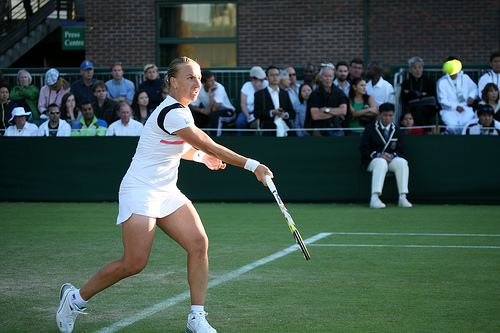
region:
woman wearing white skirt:
[132, 196, 152, 209]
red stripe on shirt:
[156, 138, 181, 144]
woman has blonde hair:
[176, 61, 181, 68]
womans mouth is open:
[191, 87, 202, 97]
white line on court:
[309, 225, 329, 241]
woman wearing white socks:
[68, 288, 81, 303]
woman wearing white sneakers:
[55, 278, 90, 331]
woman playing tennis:
[43, 53, 316, 330]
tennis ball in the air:
[442, 55, 465, 83]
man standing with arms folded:
[302, 63, 351, 133]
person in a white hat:
[6, 104, 38, 135]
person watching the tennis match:
[251, 63, 303, 137]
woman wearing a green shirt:
[342, 78, 381, 128]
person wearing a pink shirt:
[37, 69, 74, 112]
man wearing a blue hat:
[73, 58, 102, 98]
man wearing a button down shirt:
[106, 60, 139, 103]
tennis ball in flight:
[437, 54, 466, 88]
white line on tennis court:
[231, 250, 272, 286]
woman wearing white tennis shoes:
[42, 273, 230, 330]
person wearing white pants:
[363, 149, 415, 197]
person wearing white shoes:
[362, 185, 424, 215]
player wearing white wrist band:
[241, 148, 261, 176]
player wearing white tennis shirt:
[115, 93, 204, 202]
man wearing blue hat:
[76, 56, 98, 85]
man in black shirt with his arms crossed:
[305, 81, 354, 126]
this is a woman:
[32, 30, 354, 326]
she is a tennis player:
[51, 17, 322, 329]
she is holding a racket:
[139, 47, 342, 322]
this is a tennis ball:
[434, 30, 466, 87]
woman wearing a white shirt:
[116, 76, 208, 182]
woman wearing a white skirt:
[91, 155, 205, 230]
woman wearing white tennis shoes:
[48, 256, 217, 331]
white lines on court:
[103, 187, 474, 327]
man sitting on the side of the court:
[357, 95, 426, 210]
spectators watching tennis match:
[30, 22, 477, 167]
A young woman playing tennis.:
[46, 48, 341, 332]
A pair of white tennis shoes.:
[48, 280, 227, 330]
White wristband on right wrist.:
[236, 147, 258, 182]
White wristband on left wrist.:
[190, 142, 205, 167]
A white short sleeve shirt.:
[127, 97, 198, 190]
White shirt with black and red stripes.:
[125, 90, 196, 178]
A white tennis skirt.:
[116, 172, 193, 232]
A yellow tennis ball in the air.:
[440, 51, 472, 83]